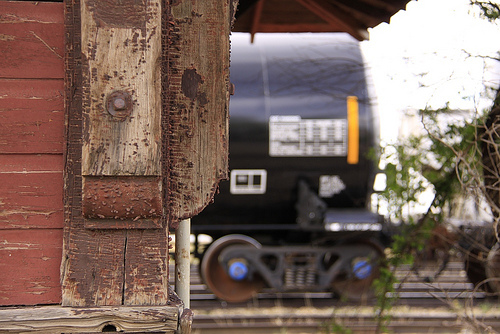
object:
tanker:
[187, 31, 381, 227]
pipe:
[173, 217, 196, 307]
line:
[343, 95, 361, 165]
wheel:
[196, 231, 265, 303]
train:
[180, 30, 391, 305]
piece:
[58, 230, 171, 307]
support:
[231, 8, 368, 35]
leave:
[339, 48, 499, 334]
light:
[363, 37, 426, 75]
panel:
[270, 115, 347, 157]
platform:
[197, 304, 500, 334]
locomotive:
[189, 32, 396, 305]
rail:
[171, 233, 500, 332]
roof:
[273, 9, 363, 29]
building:
[0, 0, 419, 334]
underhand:
[220, 4, 398, 46]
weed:
[394, 147, 460, 230]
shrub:
[367, 0, 500, 334]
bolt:
[103, 89, 136, 120]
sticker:
[265, 113, 350, 157]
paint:
[0, 4, 66, 296]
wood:
[79, 0, 158, 177]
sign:
[230, 168, 268, 194]